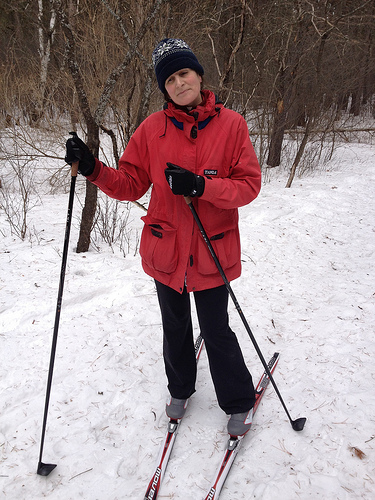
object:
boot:
[164, 395, 191, 422]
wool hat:
[152, 37, 204, 94]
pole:
[181, 195, 305, 431]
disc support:
[292, 417, 307, 432]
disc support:
[36, 459, 57, 477]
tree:
[230, 0, 368, 172]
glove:
[164, 160, 203, 197]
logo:
[204, 169, 218, 175]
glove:
[63, 135, 96, 177]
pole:
[36, 162, 80, 476]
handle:
[71, 160, 79, 176]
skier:
[62, 34, 261, 438]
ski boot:
[164, 390, 189, 420]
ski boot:
[226, 407, 254, 436]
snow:
[300, 223, 374, 429]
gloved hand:
[64, 137, 96, 177]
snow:
[248, 188, 291, 287]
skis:
[204, 353, 278, 500]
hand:
[164, 161, 192, 196]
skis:
[143, 332, 205, 500]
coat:
[83, 87, 262, 295]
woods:
[0, 2, 373, 256]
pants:
[153, 276, 257, 415]